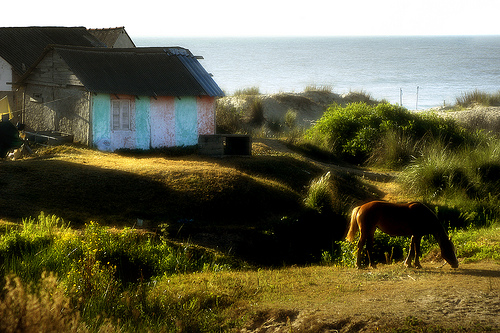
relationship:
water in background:
[128, 34, 499, 109] [0, 2, 486, 194]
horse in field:
[346, 195, 461, 272] [5, 87, 500, 331]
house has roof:
[5, 24, 223, 154] [24, 42, 231, 101]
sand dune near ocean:
[235, 80, 494, 139] [128, 34, 499, 109]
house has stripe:
[5, 24, 223, 154] [145, 95, 179, 144]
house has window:
[5, 24, 223, 154] [108, 98, 137, 133]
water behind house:
[128, 34, 499, 109] [5, 24, 223, 154]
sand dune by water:
[235, 80, 494, 139] [128, 34, 499, 109]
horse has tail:
[346, 195, 461, 272] [340, 203, 359, 242]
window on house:
[108, 98, 137, 133] [5, 24, 223, 154]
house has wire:
[5, 24, 223, 154] [2, 89, 82, 117]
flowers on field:
[57, 216, 131, 317] [5, 87, 500, 331]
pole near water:
[408, 84, 425, 107] [128, 34, 499, 109]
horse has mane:
[346, 195, 461, 272] [422, 204, 449, 241]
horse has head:
[346, 195, 461, 272] [441, 232, 459, 267]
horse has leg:
[346, 195, 461, 272] [353, 233, 374, 270]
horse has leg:
[346, 195, 461, 272] [363, 230, 383, 269]